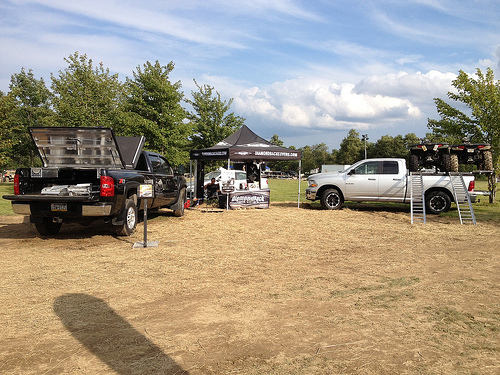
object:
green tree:
[118, 53, 205, 176]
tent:
[189, 123, 297, 209]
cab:
[307, 157, 407, 210]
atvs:
[405, 138, 495, 175]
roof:
[186, 123, 304, 160]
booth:
[188, 125, 300, 209]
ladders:
[404, 172, 428, 227]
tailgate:
[7, 186, 106, 209]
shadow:
[54, 288, 194, 375]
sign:
[130, 176, 158, 250]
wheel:
[320, 186, 345, 210]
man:
[199, 173, 221, 204]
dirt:
[0, 197, 500, 374]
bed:
[11, 167, 110, 203]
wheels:
[481, 150, 493, 175]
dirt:
[448, 151, 462, 171]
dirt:
[481, 149, 492, 169]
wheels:
[450, 152, 460, 174]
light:
[360, 132, 372, 158]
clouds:
[232, 75, 420, 132]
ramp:
[408, 170, 425, 227]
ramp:
[447, 172, 474, 225]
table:
[222, 189, 272, 209]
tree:
[113, 62, 195, 187]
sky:
[0, 0, 500, 156]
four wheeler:
[404, 141, 492, 176]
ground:
[0, 175, 500, 373]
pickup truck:
[10, 127, 191, 238]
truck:
[301, 146, 479, 213]